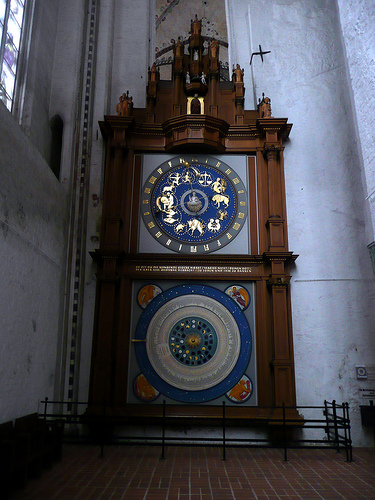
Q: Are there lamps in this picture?
A: No, there are no lamps.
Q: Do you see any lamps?
A: No, there are no lamps.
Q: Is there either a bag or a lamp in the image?
A: No, there are no lamps or bags.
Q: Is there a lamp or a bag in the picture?
A: No, there are no lamps or bags.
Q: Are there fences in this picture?
A: Yes, there is a fence.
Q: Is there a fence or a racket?
A: Yes, there is a fence.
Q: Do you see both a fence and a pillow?
A: No, there is a fence but no pillows.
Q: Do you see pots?
A: No, there are no pots.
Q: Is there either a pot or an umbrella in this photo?
A: No, there are no pots or umbrellas.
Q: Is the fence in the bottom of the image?
A: Yes, the fence is in the bottom of the image.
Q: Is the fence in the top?
A: No, the fence is in the bottom of the image.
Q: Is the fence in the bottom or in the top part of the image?
A: The fence is in the bottom of the image.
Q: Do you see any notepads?
A: No, there are no notepads.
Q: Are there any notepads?
A: No, there are no notepads.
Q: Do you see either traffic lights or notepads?
A: No, there are no notepads or traffic lights.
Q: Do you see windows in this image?
A: Yes, there is a window.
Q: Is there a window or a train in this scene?
A: Yes, there is a window.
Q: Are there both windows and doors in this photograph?
A: No, there is a window but no doors.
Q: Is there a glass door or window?
A: Yes, there is a glass window.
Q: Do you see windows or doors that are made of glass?
A: Yes, the window is made of glass.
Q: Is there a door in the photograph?
A: No, there are no doors.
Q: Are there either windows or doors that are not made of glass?
A: No, there is a window but it is made of glass.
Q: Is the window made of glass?
A: Yes, the window is made of glass.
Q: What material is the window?
A: The window is made of glass.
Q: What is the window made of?
A: The window is made of glass.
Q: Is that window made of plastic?
A: No, the window is made of glass.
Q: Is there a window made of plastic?
A: No, there is a window but it is made of glass.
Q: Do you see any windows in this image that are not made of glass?
A: No, there is a window but it is made of glass.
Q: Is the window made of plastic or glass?
A: The window is made of glass.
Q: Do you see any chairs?
A: No, there are no chairs.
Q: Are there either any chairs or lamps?
A: No, there are no chairs or lamps.